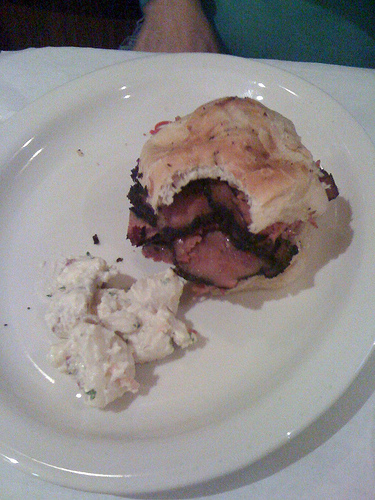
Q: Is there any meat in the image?
A: Yes, there is meat.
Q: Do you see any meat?
A: Yes, there is meat.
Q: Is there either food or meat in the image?
A: Yes, there is meat.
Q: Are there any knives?
A: No, there are no knives.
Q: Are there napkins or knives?
A: No, there are no knives or napkins.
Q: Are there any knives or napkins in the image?
A: No, there are no knives or napkins.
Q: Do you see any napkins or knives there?
A: No, there are no knives or napkins.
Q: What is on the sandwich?
A: The meat is on the sandwich.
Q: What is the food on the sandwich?
A: The food is meat.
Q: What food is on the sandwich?
A: The food is meat.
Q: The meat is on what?
A: The meat is on the sandwich.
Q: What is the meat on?
A: The meat is on the sandwich.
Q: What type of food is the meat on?
A: The meat is on the sandwich.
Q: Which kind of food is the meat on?
A: The meat is on the sandwich.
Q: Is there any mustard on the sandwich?
A: No, there is meat on the sandwich.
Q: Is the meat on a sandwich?
A: Yes, the meat is on a sandwich.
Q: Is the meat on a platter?
A: No, the meat is on a sandwich.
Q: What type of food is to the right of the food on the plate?
A: The food is meat.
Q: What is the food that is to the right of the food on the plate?
A: The food is meat.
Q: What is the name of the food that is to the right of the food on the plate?
A: The food is meat.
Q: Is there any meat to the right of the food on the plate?
A: Yes, there is meat to the right of the food.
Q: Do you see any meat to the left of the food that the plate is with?
A: No, the meat is to the right of the food.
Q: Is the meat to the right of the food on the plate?
A: Yes, the meat is to the right of the food.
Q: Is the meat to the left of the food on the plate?
A: No, the meat is to the right of the food.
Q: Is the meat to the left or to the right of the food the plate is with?
A: The meat is to the right of the food.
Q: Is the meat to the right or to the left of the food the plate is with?
A: The meat is to the right of the food.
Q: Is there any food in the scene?
A: Yes, there is food.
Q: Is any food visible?
A: Yes, there is food.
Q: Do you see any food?
A: Yes, there is food.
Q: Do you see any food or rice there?
A: Yes, there is food.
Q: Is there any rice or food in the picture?
A: Yes, there is food.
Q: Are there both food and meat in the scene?
A: Yes, there are both food and meat.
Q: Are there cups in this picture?
A: No, there are no cups.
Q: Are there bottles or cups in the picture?
A: No, there are no cups or bottles.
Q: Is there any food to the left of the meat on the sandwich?
A: Yes, there is food to the left of the meat.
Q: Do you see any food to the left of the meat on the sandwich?
A: Yes, there is food to the left of the meat.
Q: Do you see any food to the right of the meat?
A: No, the food is to the left of the meat.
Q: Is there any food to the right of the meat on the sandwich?
A: No, the food is to the left of the meat.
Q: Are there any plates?
A: Yes, there is a plate.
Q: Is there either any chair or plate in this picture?
A: Yes, there is a plate.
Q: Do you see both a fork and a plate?
A: No, there is a plate but no forks.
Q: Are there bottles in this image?
A: No, there are no bottles.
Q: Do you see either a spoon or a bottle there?
A: No, there are no bottles or spoons.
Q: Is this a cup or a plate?
A: This is a plate.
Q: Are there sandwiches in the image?
A: Yes, there is a sandwich.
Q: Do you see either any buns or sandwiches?
A: Yes, there is a sandwich.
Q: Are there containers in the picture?
A: No, there are no containers.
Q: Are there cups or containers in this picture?
A: No, there are no containers or cups.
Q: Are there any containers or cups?
A: No, there are no containers or cups.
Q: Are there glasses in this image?
A: No, there are no glasses.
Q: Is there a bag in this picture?
A: No, there are no bags.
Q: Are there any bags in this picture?
A: No, there are no bags.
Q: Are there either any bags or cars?
A: No, there are no bags or cars.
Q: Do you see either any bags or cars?
A: No, there are no bags or cars.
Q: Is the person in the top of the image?
A: Yes, the person is in the top of the image.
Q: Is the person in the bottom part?
A: No, the person is in the top of the image.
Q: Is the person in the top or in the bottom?
A: The person is in the top of the image.